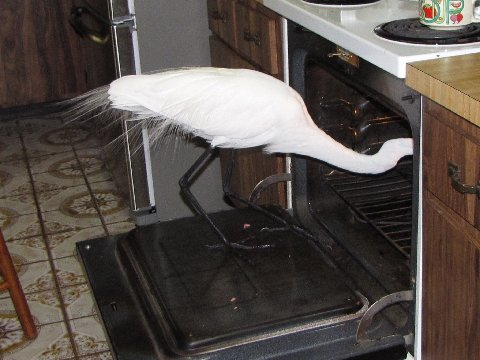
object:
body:
[150, 67, 304, 150]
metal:
[446, 162, 480, 195]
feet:
[202, 236, 270, 249]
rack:
[325, 168, 412, 258]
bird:
[54, 67, 414, 250]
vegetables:
[448, 10, 456, 24]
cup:
[419, 0, 473, 31]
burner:
[374, 17, 480, 47]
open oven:
[286, 23, 415, 336]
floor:
[0, 112, 133, 360]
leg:
[0, 234, 37, 338]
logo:
[423, 4, 437, 18]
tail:
[108, 74, 157, 108]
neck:
[310, 118, 414, 174]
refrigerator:
[69, 0, 225, 224]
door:
[78, 209, 402, 360]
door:
[65, 1, 155, 213]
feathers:
[56, 85, 201, 156]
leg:
[179, 148, 224, 237]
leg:
[223, 149, 287, 224]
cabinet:
[208, 2, 289, 209]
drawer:
[206, 0, 276, 75]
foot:
[260, 223, 313, 237]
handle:
[67, 8, 110, 43]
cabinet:
[406, 53, 480, 360]